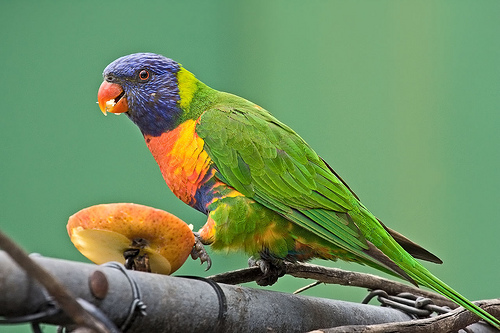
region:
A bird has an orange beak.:
[91, 62, 144, 131]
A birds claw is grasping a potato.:
[68, 195, 211, 275]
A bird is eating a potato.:
[77, 81, 162, 122]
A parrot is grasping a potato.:
[96, 53, 297, 280]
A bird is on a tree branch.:
[87, 59, 364, 294]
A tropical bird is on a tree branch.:
[106, 58, 441, 275]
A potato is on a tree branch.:
[58, 193, 206, 280]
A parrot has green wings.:
[188, 109, 414, 279]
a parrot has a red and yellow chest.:
[144, 132, 196, 205]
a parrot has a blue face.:
[98, 58, 190, 138]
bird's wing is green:
[201, 100, 391, 255]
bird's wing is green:
[187, 90, 310, 204]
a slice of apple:
[68, 183, 210, 281]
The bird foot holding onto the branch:
[249, 255, 283, 283]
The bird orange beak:
[91, 82, 126, 119]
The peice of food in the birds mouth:
[101, 95, 114, 114]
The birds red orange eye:
[140, 66, 150, 81]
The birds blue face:
[100, 55, 179, 132]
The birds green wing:
[198, 100, 490, 328]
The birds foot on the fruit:
[184, 225, 212, 267]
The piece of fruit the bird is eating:
[73, 211, 192, 268]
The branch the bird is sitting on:
[9, 247, 497, 328]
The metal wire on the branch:
[106, 259, 155, 328]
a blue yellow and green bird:
[97, 51, 493, 327]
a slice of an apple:
[67, 203, 193, 278]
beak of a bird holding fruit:
[97, 80, 128, 118]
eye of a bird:
[137, 69, 149, 79]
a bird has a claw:
[191, 229, 213, 269]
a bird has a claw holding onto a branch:
[246, 256, 283, 286]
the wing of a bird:
[198, 107, 418, 289]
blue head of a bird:
[99, 53, 181, 135]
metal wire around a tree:
[97, 260, 144, 328]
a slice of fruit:
[63, 200, 188, 275]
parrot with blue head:
[66, 46, 498, 331]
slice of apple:
[50, 198, 205, 277]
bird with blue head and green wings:
[84, 45, 497, 331]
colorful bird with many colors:
[91, 45, 499, 331]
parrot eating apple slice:
[59, 43, 233, 278]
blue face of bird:
[87, 40, 184, 134]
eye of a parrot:
[132, 62, 158, 87]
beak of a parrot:
[95, 75, 130, 120]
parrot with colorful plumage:
[93, 47, 493, 332]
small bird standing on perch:
[92, 46, 447, 285]